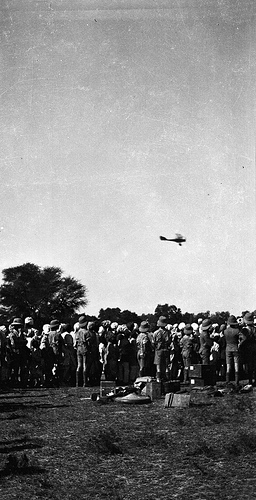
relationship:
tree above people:
[3, 258, 88, 326] [26, 306, 196, 374]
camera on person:
[219, 320, 245, 346] [220, 315, 244, 377]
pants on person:
[220, 344, 241, 363] [212, 319, 249, 381]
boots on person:
[176, 352, 253, 382] [212, 319, 249, 381]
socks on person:
[212, 357, 250, 383] [212, 319, 249, 381]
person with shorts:
[135, 320, 150, 379] [153, 349, 170, 365]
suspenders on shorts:
[154, 329, 168, 345] [153, 349, 170, 365]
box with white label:
[188, 362, 214, 377] [190, 379, 194, 384]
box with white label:
[188, 362, 214, 377] [188, 365, 193, 369]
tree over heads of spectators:
[3, 258, 88, 326] [1, 313, 255, 391]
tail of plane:
[159, 236, 167, 240] [159, 233, 186, 245]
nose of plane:
[180, 235, 187, 242] [157, 232, 189, 246]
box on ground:
[186, 362, 214, 377] [0, 378, 254, 498]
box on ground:
[189, 378, 216, 389] [0, 378, 254, 498]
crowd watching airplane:
[12, 316, 247, 380] [156, 230, 192, 248]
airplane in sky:
[159, 232, 187, 247] [0, 0, 255, 317]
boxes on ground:
[89, 369, 179, 407] [0, 378, 254, 498]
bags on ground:
[152, 345, 235, 398] [0, 378, 254, 498]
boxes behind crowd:
[89, 369, 179, 407] [82, 299, 237, 375]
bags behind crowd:
[152, 345, 235, 398] [82, 299, 237, 375]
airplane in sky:
[155, 229, 188, 248] [0, 0, 255, 317]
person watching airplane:
[75, 314, 91, 389] [151, 226, 189, 252]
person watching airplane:
[224, 314, 240, 384] [158, 232, 187, 246]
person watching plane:
[128, 317, 153, 391] [149, 223, 192, 249]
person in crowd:
[128, 317, 153, 391] [3, 307, 229, 405]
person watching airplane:
[149, 308, 177, 381] [160, 233, 187, 245]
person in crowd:
[149, 308, 177, 381] [0, 312, 255, 388]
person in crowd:
[180, 322, 196, 382] [0, 312, 255, 388]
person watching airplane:
[180, 322, 196, 382] [160, 233, 186, 247]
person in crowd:
[222, 316, 242, 388] [0, 312, 255, 388]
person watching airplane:
[222, 316, 242, 388] [158, 230, 187, 247]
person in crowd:
[235, 326, 255, 387] [0, 312, 255, 388]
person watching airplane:
[235, 326, 255, 387] [159, 232, 187, 247]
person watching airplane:
[74, 314, 91, 385] [157, 230, 187, 249]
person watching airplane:
[44, 318, 63, 383] [157, 230, 187, 249]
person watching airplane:
[198, 317, 214, 364] [157, 230, 187, 249]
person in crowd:
[74, 314, 91, 385] [0, 312, 255, 388]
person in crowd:
[224, 314, 240, 384] [0, 312, 255, 388]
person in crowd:
[44, 318, 63, 383] [0, 312, 255, 388]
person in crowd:
[198, 317, 214, 364] [0, 312, 255, 388]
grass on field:
[3, 385, 247, 499] [2, 367, 255, 499]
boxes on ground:
[129, 373, 185, 395] [0, 378, 254, 498]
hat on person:
[139, 320, 149, 332] [136, 319, 152, 374]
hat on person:
[228, 315, 239, 327] [223, 316, 243, 375]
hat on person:
[201, 320, 211, 332] [199, 317, 213, 387]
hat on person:
[181, 321, 194, 337] [182, 325, 195, 382]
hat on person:
[158, 311, 169, 328] [155, 317, 175, 382]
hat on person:
[172, 322, 182, 330] [162, 317, 216, 382]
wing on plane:
[174, 233, 182, 237] [159, 233, 186, 245]